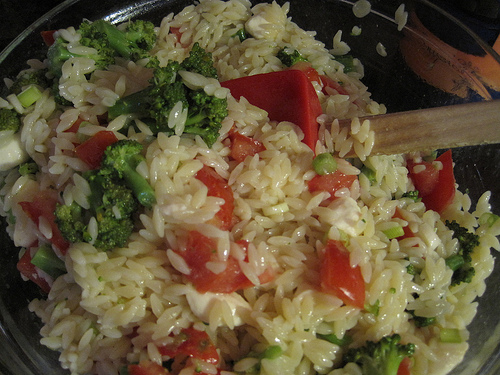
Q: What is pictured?
A: Food.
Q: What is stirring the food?
A: Spatula.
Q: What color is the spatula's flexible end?
A: Red.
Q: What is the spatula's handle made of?
A: Wood.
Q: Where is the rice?
A: Mixed in the bowl.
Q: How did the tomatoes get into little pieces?
A: Someone cut them.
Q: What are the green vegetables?
A: Broccoli.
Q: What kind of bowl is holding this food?
A: Glass.